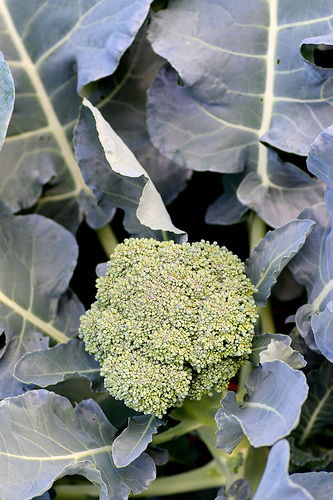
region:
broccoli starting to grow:
[41, 212, 295, 435]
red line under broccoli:
[211, 372, 244, 404]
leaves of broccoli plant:
[3, 175, 330, 487]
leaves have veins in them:
[2, 398, 174, 497]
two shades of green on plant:
[9, 216, 306, 475]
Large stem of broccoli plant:
[80, 298, 267, 499]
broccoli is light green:
[46, 232, 301, 455]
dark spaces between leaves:
[35, 192, 295, 432]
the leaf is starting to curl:
[69, 91, 196, 282]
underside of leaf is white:
[244, 321, 311, 450]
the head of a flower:
[80, 240, 270, 415]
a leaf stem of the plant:
[9, 45, 90, 211]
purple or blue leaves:
[59, 45, 273, 219]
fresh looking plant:
[40, 326, 309, 490]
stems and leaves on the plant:
[105, 394, 273, 490]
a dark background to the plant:
[65, 174, 255, 259]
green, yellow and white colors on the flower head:
[90, 234, 266, 313]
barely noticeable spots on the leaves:
[31, 66, 107, 148]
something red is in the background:
[207, 364, 252, 415]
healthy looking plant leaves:
[6, 214, 78, 393]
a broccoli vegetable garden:
[0, 0, 332, 499]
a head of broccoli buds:
[78, 237, 258, 418]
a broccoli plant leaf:
[0, 389, 155, 499]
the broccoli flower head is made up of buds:
[77, 237, 259, 417]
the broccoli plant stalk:
[196, 396, 247, 498]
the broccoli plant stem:
[154, 459, 221, 498]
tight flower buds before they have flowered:
[78, 236, 259, 418]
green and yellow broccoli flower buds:
[79, 238, 257, 417]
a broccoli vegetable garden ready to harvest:
[0, 0, 332, 499]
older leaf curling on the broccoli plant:
[73, 96, 188, 242]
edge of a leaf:
[108, 456, 133, 469]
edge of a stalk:
[190, 466, 200, 477]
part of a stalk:
[181, 460, 198, 484]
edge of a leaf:
[253, 433, 287, 452]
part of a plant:
[145, 394, 172, 430]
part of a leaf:
[308, 412, 322, 445]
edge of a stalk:
[179, 478, 210, 493]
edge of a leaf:
[70, 452, 92, 478]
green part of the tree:
[54, 221, 263, 424]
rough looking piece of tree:
[134, 282, 202, 351]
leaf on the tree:
[4, 410, 100, 487]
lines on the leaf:
[19, 395, 55, 425]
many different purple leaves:
[34, 101, 269, 223]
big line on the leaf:
[243, 9, 297, 106]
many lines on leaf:
[13, 416, 79, 451]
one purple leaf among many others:
[0, 231, 85, 325]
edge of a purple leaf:
[132, 89, 180, 133]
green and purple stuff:
[41, 203, 285, 436]